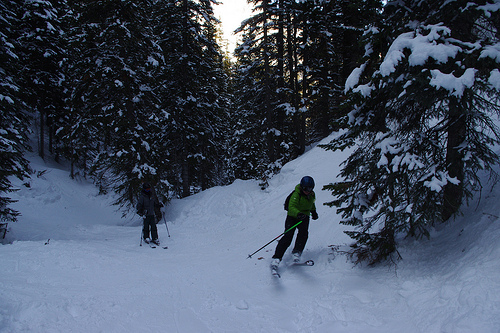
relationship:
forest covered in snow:
[4, 2, 499, 259] [38, 182, 318, 314]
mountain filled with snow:
[1, 78, 496, 324] [38, 182, 318, 314]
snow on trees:
[38, 182, 318, 314] [19, 18, 469, 166]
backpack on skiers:
[281, 188, 298, 209] [272, 176, 318, 266]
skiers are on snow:
[124, 170, 339, 283] [38, 182, 318, 314]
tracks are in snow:
[208, 284, 373, 315] [38, 182, 318, 314]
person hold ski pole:
[128, 165, 178, 254] [159, 208, 175, 238]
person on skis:
[128, 165, 178, 254] [136, 203, 173, 259]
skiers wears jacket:
[272, 176, 318, 266] [287, 189, 317, 222]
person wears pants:
[128, 165, 178, 254] [137, 214, 164, 245]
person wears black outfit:
[128, 165, 178, 254] [136, 193, 158, 217]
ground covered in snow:
[13, 217, 498, 321] [38, 182, 318, 314]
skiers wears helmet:
[272, 176, 318, 266] [298, 174, 315, 188]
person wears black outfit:
[128, 165, 178, 254] [132, 190, 168, 246]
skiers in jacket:
[272, 176, 318, 266] [287, 189, 317, 222]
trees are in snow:
[19, 18, 469, 166] [38, 182, 318, 314]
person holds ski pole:
[128, 165, 178, 254] [159, 208, 175, 238]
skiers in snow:
[272, 176, 318, 266] [38, 182, 318, 314]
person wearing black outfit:
[128, 165, 178, 254] [132, 190, 168, 246]